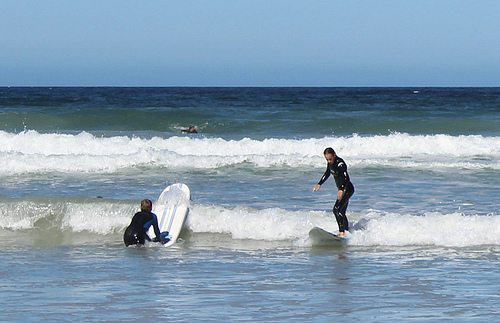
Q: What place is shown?
A: It is an ocean.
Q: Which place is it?
A: It is an ocean.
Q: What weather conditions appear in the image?
A: It is cloudless.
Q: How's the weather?
A: It is cloudless.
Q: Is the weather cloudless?
A: Yes, it is cloudless.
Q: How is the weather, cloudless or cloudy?
A: It is cloudless.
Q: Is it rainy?
A: No, it is cloudless.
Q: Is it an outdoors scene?
A: Yes, it is outdoors.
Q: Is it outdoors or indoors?
A: It is outdoors.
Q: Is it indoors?
A: No, it is outdoors.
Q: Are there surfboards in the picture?
A: Yes, there is a surfboard.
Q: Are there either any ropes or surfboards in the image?
A: Yes, there is a surfboard.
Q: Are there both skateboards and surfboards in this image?
A: No, there is a surfboard but no skateboards.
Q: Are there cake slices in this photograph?
A: No, there are no cake slices.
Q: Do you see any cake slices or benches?
A: No, there are no cake slices or benches.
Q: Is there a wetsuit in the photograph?
A: Yes, there is a wetsuit.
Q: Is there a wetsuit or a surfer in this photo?
A: Yes, there is a wetsuit.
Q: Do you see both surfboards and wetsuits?
A: Yes, there are both a wetsuit and a surfboard.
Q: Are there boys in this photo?
A: No, there are no boys.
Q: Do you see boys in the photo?
A: No, there are no boys.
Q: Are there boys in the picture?
A: No, there are no boys.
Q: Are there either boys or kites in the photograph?
A: No, there are no boys or kites.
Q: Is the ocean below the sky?
A: Yes, the ocean is below the sky.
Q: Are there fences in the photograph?
A: No, there are no fences.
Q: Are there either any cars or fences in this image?
A: No, there are no fences or cars.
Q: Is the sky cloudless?
A: Yes, the sky is cloudless.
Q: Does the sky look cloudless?
A: Yes, the sky is cloudless.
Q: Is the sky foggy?
A: No, the sky is cloudless.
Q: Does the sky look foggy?
A: No, the sky is cloudless.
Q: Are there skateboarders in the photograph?
A: No, there are no skateboarders.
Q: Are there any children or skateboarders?
A: No, there are no skateboarders or children.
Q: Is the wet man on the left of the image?
A: Yes, the man is on the left of the image.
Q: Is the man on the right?
A: No, the man is on the left of the image.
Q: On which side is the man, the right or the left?
A: The man is on the left of the image.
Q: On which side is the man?
A: The man is on the left of the image.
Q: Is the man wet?
A: Yes, the man is wet.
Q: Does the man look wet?
A: Yes, the man is wet.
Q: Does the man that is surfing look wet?
A: Yes, the man is wet.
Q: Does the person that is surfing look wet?
A: Yes, the man is wet.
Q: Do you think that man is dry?
A: No, the man is wet.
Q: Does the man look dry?
A: No, the man is wet.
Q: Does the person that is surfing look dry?
A: No, the man is wet.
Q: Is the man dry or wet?
A: The man is wet.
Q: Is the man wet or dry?
A: The man is wet.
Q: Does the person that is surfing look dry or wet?
A: The man is wet.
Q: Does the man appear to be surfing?
A: Yes, the man is surfing.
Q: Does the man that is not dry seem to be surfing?
A: Yes, the man is surfing.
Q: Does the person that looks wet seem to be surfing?
A: Yes, the man is surfing.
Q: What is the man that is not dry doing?
A: The man is surfing.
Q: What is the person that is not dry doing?
A: The man is surfing.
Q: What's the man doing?
A: The man is surfing.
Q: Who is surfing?
A: The man is surfing.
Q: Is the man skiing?
A: No, the man is surfing.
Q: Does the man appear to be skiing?
A: No, the man is surfing.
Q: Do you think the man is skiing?
A: No, the man is surfing.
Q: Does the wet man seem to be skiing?
A: No, the man is surfing.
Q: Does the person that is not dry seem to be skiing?
A: No, the man is surfing.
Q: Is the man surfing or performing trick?
A: The man is surfing.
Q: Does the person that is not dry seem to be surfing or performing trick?
A: The man is surfing.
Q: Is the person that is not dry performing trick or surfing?
A: The man is surfing.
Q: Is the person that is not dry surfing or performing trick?
A: The man is surfing.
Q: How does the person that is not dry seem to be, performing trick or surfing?
A: The man is surfing.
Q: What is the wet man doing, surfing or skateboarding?
A: The man is surfing.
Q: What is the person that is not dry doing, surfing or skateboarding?
A: The man is surfing.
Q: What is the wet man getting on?
A: The man is getting on the surfboard.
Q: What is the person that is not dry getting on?
A: The man is getting on the surfboard.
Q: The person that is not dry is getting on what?
A: The man is getting on the surfboard.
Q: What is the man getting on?
A: The man is getting on the surfboard.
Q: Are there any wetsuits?
A: Yes, there is a wetsuit.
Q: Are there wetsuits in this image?
A: Yes, there is a wetsuit.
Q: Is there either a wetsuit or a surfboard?
A: Yes, there is a wetsuit.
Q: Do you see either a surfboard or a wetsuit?
A: Yes, there is a wetsuit.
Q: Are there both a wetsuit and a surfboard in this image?
A: Yes, there are both a wetsuit and a surfboard.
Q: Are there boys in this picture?
A: No, there are no boys.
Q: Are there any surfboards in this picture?
A: Yes, there is a surfboard.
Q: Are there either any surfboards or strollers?
A: Yes, there is a surfboard.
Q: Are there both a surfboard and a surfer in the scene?
A: Yes, there are both a surfboard and a surfer.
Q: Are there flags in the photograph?
A: No, there are no flags.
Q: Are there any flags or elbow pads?
A: No, there are no flags or elbow pads.